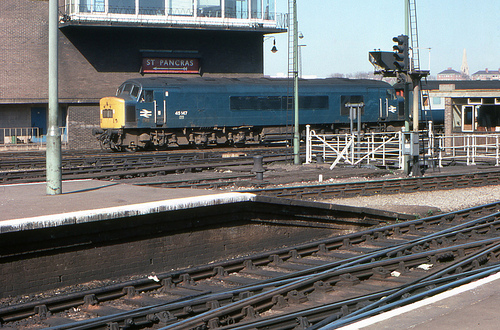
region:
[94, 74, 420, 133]
the train is blue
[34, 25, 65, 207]
the pole is gray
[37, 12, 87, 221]
the pole is gray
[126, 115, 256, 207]
Section of a rail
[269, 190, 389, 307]
Section of a rail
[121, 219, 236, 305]
Section of a rail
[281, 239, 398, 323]
Section of a rail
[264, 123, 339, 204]
Section of a rail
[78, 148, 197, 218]
Section of a rail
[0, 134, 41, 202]
Section of a rail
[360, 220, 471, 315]
Section of a rail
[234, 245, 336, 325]
Section of a rail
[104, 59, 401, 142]
Blue and yellow locomotive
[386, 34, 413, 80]
traffic light on a pole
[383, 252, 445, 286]
paper on the train tracks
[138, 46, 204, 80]
sign on a building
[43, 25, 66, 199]
pole on a train platform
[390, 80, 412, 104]
street sign on a pole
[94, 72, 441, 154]
Train on the tracks.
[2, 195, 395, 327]
Hole in the ground.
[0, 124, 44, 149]
Railing in front of the building.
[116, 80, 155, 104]
Windows on the train.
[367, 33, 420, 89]
Traffic signal on the post.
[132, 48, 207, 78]
Sign on the building.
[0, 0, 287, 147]
Building in the background.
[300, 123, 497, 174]
White fence in between the tracks.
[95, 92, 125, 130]
Yellow front on the train.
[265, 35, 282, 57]
Light hanging from the building.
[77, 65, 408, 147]
train at the building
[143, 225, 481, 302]
train tracks between the platforms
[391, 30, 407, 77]
traffic light for the trains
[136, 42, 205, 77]
red and white sign on the building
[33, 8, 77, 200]
pole on the platform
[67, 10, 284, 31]
wire around the windows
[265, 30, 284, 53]
light attached to the building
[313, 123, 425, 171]
white rails near the tracks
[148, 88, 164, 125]
door on the engine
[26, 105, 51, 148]
blue door on the building